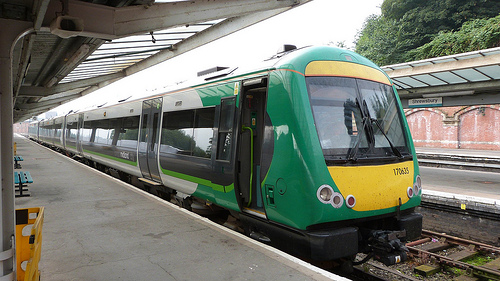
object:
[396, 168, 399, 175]
numbers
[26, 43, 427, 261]
train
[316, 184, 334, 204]
lights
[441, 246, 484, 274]
tracks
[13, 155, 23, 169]
benches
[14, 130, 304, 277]
train stop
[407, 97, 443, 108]
sign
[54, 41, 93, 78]
light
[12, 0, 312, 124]
ceiling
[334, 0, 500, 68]
trees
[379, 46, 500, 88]
roof top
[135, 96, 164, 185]
doors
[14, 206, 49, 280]
moving crates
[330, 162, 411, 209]
section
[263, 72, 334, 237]
section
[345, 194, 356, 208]
lights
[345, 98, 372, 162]
wipers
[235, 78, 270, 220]
door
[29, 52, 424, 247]
train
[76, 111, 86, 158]
doors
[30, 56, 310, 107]
top section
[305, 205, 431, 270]
front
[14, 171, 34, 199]
benches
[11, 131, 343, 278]
platform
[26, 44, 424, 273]
train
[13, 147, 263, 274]
platform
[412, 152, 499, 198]
platform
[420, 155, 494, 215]
platform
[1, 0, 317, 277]
shelter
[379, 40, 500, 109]
shelter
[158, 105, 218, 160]
train window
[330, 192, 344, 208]
headlight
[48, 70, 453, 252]
train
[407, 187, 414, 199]
headlight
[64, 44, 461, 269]
train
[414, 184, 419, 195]
headlight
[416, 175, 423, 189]
headlight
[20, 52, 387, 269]
train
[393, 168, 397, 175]
number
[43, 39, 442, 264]
train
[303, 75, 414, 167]
windshield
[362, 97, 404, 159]
wipers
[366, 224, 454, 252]
tracks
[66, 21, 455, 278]
train